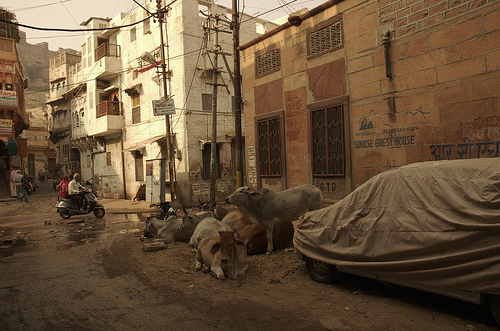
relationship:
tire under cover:
[270, 247, 341, 293] [277, 147, 492, 286]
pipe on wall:
[375, 33, 406, 91] [322, 21, 480, 194]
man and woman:
[79, 172, 88, 184] [62, 176, 71, 182]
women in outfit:
[62, 175, 74, 195] [64, 184, 72, 194]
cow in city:
[197, 158, 346, 268] [21, 24, 450, 309]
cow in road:
[197, 158, 346, 268] [0, 178, 499, 331]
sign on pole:
[114, 75, 182, 146] [224, 26, 261, 183]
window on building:
[305, 17, 341, 48] [209, 6, 450, 218]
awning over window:
[228, 10, 310, 94] [305, 17, 341, 48]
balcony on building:
[65, 34, 122, 90] [209, 6, 450, 218]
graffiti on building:
[419, 144, 466, 157] [209, 6, 450, 218]